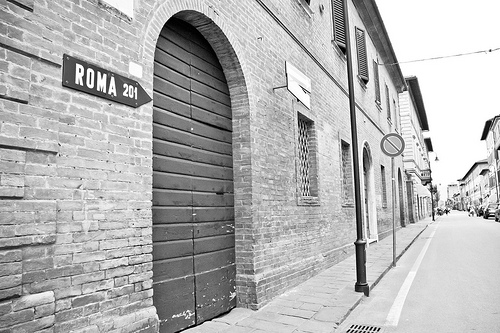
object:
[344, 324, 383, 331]
sewer grate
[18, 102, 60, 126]
brick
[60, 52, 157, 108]
arrow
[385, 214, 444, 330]
line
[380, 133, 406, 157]
sign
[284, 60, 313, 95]
sign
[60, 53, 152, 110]
sign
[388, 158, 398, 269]
pole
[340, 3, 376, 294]
lamp pole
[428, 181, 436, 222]
lamp pole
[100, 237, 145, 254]
brick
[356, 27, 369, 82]
shutters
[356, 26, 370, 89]
window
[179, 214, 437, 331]
sidewalk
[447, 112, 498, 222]
building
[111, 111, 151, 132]
brick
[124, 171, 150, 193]
brick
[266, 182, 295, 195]
brick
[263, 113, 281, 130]
brick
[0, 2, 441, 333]
brick building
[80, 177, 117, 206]
brick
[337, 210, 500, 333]
road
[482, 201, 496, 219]
car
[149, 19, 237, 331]
door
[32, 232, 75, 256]
brick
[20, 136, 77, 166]
brick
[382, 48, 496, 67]
cable